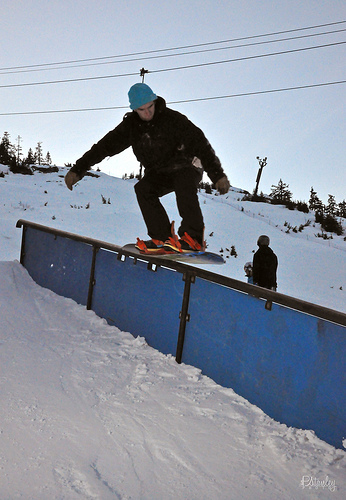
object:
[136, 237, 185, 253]
strap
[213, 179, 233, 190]
gloves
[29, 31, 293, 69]
cable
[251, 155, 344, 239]
trees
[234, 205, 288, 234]
slope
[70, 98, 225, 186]
jacket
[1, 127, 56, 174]
pine trees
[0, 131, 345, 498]
hilltop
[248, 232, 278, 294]
skier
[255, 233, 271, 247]
ski helmet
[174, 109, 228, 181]
arm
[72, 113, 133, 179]
arm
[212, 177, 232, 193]
hand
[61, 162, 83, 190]
hand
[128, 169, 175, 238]
leg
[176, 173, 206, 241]
leg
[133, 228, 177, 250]
foot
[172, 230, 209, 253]
foot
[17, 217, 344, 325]
rail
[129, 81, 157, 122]
head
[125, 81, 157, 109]
cap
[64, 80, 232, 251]
man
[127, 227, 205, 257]
snowboarding boots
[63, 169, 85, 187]
ski glove